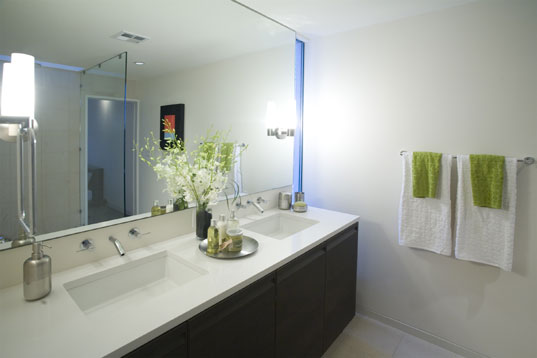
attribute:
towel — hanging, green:
[408, 148, 446, 202]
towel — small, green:
[409, 150, 441, 202]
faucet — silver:
[103, 236, 132, 258]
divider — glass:
[72, 48, 137, 232]